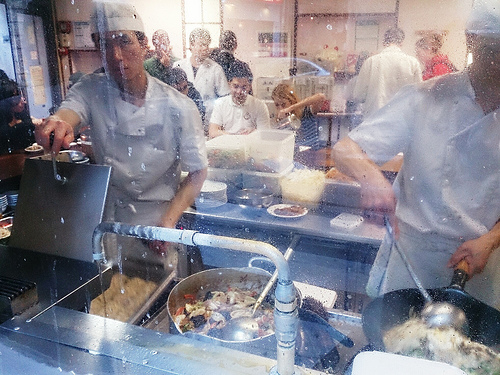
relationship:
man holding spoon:
[330, 2, 497, 311] [384, 217, 470, 341]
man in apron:
[34, 2, 208, 273] [106, 200, 189, 281]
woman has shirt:
[269, 83, 328, 148] [295, 104, 321, 151]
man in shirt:
[34, 2, 208, 273] [56, 66, 210, 203]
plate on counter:
[267, 204, 310, 219] [184, 194, 384, 245]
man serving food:
[330, 2, 497, 311] [383, 305, 499, 374]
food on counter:
[283, 170, 328, 210] [184, 194, 384, 245]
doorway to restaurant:
[0, 0, 57, 120] [0, 1, 499, 235]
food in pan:
[383, 305, 499, 374] [363, 260, 499, 373]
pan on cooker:
[363, 260, 499, 373] [142, 286, 499, 373]